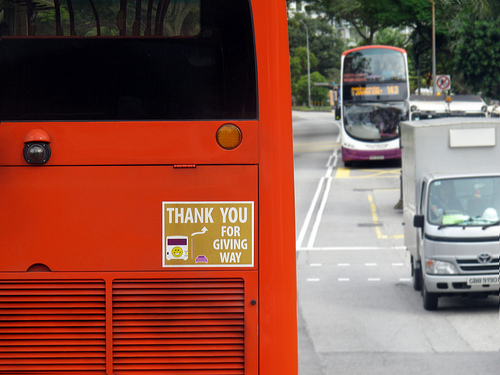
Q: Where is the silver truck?
A: On road.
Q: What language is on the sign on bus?
A: English.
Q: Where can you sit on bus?
A: First or second level.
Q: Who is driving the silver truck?
A: A person.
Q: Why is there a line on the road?
A: Direct traffic.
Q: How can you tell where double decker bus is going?
A: Words on front of bus in yellow.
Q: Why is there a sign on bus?
A: Politeness and warning.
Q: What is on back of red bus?
A: Grates.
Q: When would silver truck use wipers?
A: When it rains.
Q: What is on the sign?
A: Letters.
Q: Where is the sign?
A: Back of the bus.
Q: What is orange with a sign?
A: The bus.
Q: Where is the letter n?
A: Back of the bus.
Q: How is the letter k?
A: Capital.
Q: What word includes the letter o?
A: YOU.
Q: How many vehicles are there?
A: 3.